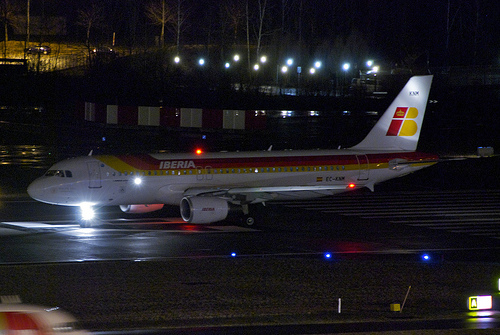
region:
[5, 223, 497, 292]
blue lights on a runway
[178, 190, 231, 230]
left side jet engine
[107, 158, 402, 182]
windows on a passenger plane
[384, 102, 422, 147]
logo for air iberia plane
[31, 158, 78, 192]
pilot's area on airplane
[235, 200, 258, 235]
landing gear on plane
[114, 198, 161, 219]
right engine on passenger plane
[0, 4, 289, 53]
line of trees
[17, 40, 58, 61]
car on street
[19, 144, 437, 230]
plane taxiing on runway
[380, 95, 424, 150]
red and yellow B on white background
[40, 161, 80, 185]
Front window of airplane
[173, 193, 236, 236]
Right engine or airplane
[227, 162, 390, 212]
Right wing of airplane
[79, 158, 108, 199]
Front door of airplane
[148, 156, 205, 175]
White IBERIA sign on Airplane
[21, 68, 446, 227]
Aircraft taxing on runway at night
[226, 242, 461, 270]
Three blue lights on pavement at night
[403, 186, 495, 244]
Right lines painted on pavement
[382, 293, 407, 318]
Yellow box on field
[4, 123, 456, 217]
an airplane on a runway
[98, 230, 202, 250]
black tarmac of the runway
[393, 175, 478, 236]
white stripes of the runway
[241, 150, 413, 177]
red and yellow stripes on the plane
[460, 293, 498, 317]
yellow sign with the letter A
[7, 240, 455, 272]
blue lights on the side of the runway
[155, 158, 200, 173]
white lettering on the side of the plane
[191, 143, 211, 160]
red light on the top of the plane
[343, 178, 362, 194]
red light on the bottom of the plane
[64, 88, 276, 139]
a red building with white doors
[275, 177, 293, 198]
edge of a wing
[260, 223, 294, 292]
part of a runway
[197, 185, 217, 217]
part of an engine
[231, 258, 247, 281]
part of a floor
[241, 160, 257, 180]
part of a plane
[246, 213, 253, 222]
part of a wheel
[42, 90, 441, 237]
a white plane on a runway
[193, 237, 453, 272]
blue lights on the runway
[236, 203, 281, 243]
landing gear of the plane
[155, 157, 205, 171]
white lettering on the plane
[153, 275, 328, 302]
tan grass of the courtyard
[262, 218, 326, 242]
black tarmac of the runway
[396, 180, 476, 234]
white stripes on the tarmac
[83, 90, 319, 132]
a red and white building next to the runway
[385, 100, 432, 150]
red and yellow airline logo on the tail fin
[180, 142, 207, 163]
red light on top of the plane